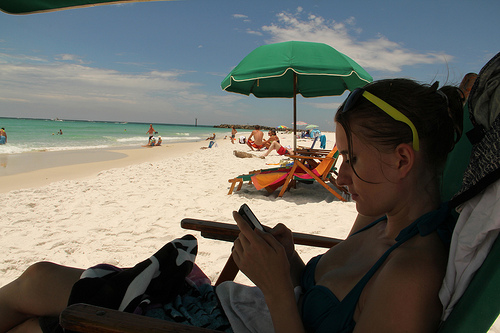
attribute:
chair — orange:
[225, 139, 350, 204]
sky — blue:
[396, 14, 495, 59]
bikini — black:
[288, 221, 416, 331]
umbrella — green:
[212, 28, 397, 122]